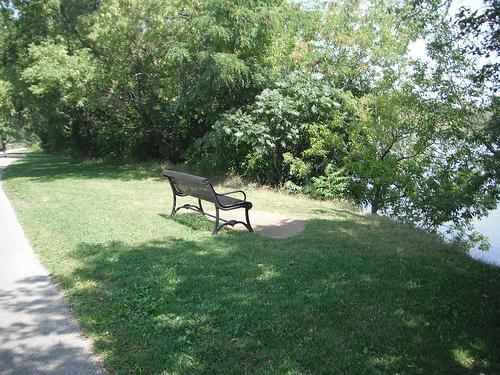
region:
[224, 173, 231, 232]
the chair is steel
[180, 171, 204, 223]
the chair is steel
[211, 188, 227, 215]
the chair is steel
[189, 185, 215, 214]
the chair is steel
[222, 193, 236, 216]
the chair is steel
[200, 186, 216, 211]
the chair is steel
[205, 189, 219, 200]
the chair is steel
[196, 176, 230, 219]
the chair is steel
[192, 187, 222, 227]
the chair is steel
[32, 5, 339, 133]
A lot of trees and plants.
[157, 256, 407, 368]
The grass is green.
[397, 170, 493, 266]
Water to the right.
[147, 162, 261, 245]
A black bench.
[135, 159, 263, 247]
The bench is metal.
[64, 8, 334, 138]
The trees are green.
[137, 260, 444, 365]
This grass is in the shade.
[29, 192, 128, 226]
This grass is in the sunlight.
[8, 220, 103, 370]
A sidewalk is shown.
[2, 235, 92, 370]
The sidewalk is gray.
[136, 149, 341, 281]
the bench is black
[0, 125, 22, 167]
person walking at the sidewalk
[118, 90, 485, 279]
bench is facing the water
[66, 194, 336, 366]
shadows of the trees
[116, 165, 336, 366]
shadows on the ground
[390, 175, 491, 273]
the water is calm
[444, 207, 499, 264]
the water is blue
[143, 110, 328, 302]
the bench is made of steel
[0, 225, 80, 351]
the sidewalk is concrete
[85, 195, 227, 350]
grasses on the ground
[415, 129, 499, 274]
water behind the tree leaves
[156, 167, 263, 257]
black park bench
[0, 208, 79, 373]
a gray sidewalk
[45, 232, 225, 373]
shadow from the trees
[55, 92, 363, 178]
bunch of trees and bushes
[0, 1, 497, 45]
blue sky behind trees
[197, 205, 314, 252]
brown patch of dirt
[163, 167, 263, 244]
black metal sitting bench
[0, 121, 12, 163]
person walking on path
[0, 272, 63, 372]
shadows from tree leaves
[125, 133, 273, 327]
the bench is black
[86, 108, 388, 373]
the bench is black